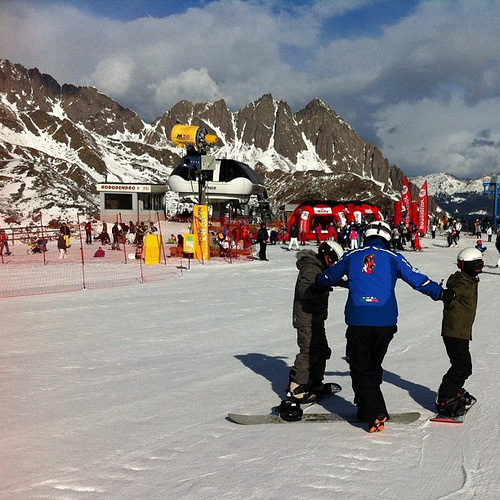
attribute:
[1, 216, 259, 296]
fencing — red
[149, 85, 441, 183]
rocks — JAGGED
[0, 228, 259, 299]
net — red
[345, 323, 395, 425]
pants — black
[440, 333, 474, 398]
pants — black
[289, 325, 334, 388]
pants — black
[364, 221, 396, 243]
helmet — white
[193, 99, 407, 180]
rocks — huge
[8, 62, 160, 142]
rocks — huge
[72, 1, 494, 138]
sky — cloudy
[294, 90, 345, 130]
mountain top — snowy, jagged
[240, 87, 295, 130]
mountain top — snowy, jagged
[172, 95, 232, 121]
mountain top — snowy, jagged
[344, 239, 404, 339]
coat — blue, white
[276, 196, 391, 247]
tent — red, white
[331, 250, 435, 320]
jacket — man's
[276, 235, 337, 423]
man — young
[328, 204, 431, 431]
man — young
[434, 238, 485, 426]
man — young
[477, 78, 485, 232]
pylon — blue